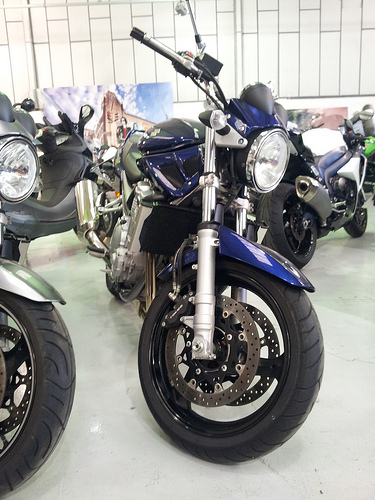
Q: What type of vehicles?
A: Motorcycles.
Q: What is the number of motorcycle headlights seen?
A: 2.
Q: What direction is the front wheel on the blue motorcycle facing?
A: Right.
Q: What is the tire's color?
A: Black.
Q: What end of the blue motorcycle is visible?
A: Front.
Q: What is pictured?
A: Motorcycles.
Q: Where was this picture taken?
A: A showroom displaying motorcycles.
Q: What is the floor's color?
A: White.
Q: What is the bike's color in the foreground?
A: Blue.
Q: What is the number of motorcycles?
A: At least five.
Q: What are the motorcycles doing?
A: Parked.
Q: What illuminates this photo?
A: Indoor lighting.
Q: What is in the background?
A: A painting.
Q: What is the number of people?
A: Zero.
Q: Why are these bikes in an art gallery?
A: They are custom made.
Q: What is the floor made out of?
A: Painted cement.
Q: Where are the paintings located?
A: Against the wall.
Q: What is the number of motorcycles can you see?
A: 4.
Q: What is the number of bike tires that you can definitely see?
A: 6.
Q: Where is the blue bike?
A: Front and center.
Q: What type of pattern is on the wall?
A: Slat panel.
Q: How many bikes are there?
A: 3.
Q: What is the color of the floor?
A: Grey.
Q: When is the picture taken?
A: Daytime.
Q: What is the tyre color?
A: Black.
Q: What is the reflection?
A: Light.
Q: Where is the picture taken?
A: At a motorcycle shop.